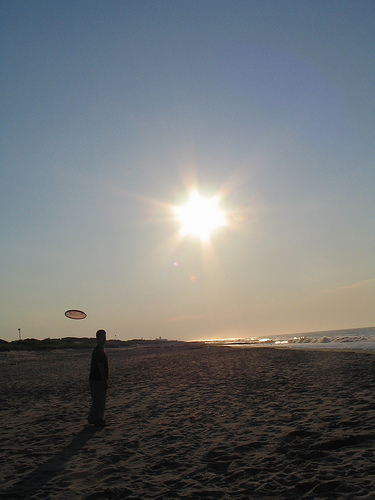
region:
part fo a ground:
[233, 414, 257, 448]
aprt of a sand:
[256, 420, 275, 446]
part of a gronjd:
[237, 431, 252, 449]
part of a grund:
[241, 384, 255, 414]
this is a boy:
[74, 320, 121, 417]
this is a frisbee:
[63, 306, 90, 319]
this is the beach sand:
[198, 381, 335, 494]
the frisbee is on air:
[56, 306, 89, 324]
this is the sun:
[167, 188, 240, 239]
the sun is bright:
[164, 169, 248, 254]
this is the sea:
[313, 323, 343, 340]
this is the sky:
[19, 185, 112, 274]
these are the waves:
[317, 333, 345, 342]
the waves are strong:
[303, 335, 326, 343]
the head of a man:
[90, 319, 121, 376]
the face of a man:
[90, 321, 119, 344]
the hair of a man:
[91, 321, 112, 346]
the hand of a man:
[95, 368, 137, 400]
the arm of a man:
[87, 355, 117, 386]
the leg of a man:
[73, 378, 121, 434]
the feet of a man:
[70, 398, 131, 442]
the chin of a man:
[89, 318, 119, 345]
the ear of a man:
[89, 326, 112, 367]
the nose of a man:
[93, 326, 115, 351]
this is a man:
[79, 324, 122, 422]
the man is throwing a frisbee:
[71, 327, 116, 424]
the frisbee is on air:
[64, 305, 90, 320]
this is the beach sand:
[170, 378, 293, 491]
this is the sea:
[300, 331, 339, 347]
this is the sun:
[172, 182, 236, 238]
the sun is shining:
[169, 185, 236, 240]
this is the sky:
[14, 85, 122, 221]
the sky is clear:
[24, 48, 126, 177]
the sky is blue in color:
[157, 40, 290, 137]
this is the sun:
[176, 166, 237, 249]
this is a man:
[84, 317, 135, 424]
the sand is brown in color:
[233, 379, 312, 445]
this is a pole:
[15, 324, 24, 339]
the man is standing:
[79, 313, 127, 412]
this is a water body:
[301, 331, 358, 345]